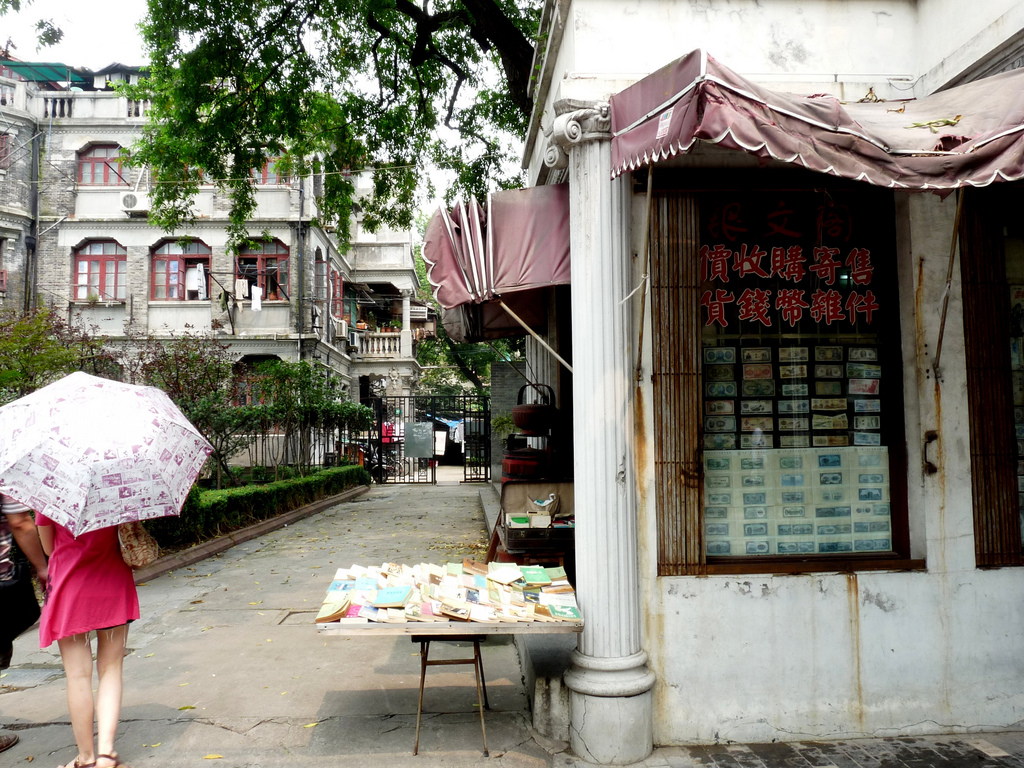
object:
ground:
[304, 504, 389, 547]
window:
[137, 224, 217, 317]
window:
[230, 124, 302, 189]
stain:
[911, 288, 954, 512]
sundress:
[33, 525, 143, 649]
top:
[48, 363, 120, 417]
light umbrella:
[0, 362, 237, 545]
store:
[419, 0, 1024, 768]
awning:
[595, 39, 1022, 200]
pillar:
[540, 99, 660, 768]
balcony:
[334, 243, 422, 375]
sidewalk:
[239, 503, 306, 750]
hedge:
[213, 472, 320, 520]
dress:
[17, 482, 162, 650]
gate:
[370, 388, 518, 498]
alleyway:
[273, 492, 465, 554]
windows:
[651, 147, 1023, 579]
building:
[0, 43, 424, 483]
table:
[310, 552, 592, 751]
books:
[309, 595, 359, 626]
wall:
[696, 593, 1000, 725]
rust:
[832, 575, 902, 729]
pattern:
[119, 480, 138, 501]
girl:
[13, 465, 175, 766]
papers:
[369, 578, 418, 612]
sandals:
[88, 748, 129, 764]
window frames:
[69, 245, 137, 310]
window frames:
[61, 135, 137, 204]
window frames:
[228, 249, 297, 305]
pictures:
[695, 329, 899, 574]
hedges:
[200, 495, 224, 533]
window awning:
[599, 48, 1016, 189]